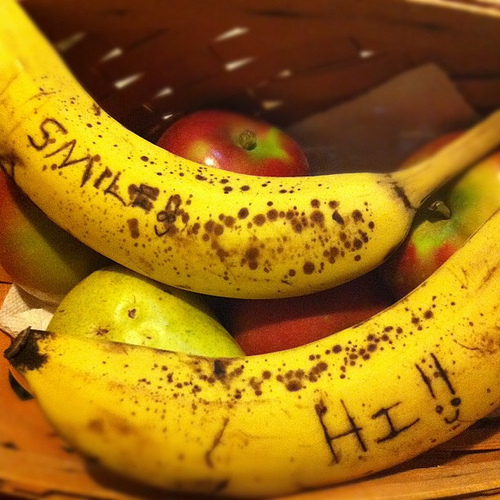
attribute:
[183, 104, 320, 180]
apple — green, red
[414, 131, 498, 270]
apple — red, green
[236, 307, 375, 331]
apple — red, green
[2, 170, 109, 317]
apple — red, green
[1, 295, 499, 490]
banana — over ripe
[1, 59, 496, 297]
banana — over ripe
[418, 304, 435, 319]
spot — brown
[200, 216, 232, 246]
spot — brown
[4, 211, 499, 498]
banana — over ripe, brown, yellow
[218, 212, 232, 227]
spot — brown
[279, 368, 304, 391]
spot — brown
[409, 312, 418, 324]
spot — brown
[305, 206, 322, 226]
spot — brown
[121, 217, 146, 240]
spot — brown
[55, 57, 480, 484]
banana — over ripe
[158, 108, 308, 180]
red apple — green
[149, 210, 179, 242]
face — smiling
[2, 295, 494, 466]
banana — yellow 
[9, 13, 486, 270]
banana — yellow 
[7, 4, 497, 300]
banana — yellow, over ripe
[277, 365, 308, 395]
spot — brown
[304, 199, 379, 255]
spot — brown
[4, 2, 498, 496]
basket — full